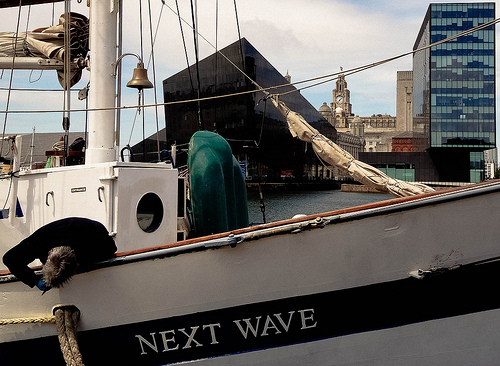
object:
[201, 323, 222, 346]
writing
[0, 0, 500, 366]
boat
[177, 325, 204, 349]
word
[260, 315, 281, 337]
word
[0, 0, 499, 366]
part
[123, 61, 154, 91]
bell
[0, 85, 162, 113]
clouds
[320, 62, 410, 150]
land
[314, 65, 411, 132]
building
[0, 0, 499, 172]
background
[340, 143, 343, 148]
windows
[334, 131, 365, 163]
building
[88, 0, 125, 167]
pole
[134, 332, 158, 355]
letters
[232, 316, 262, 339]
lettering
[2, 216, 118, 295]
man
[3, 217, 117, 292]
black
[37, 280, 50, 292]
glove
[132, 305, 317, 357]
next wave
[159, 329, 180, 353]
letters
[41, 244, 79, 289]
hair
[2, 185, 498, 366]
side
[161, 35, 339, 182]
building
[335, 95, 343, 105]
clock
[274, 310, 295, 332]
letter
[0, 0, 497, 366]
picture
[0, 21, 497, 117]
rope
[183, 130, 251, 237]
seat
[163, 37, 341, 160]
glass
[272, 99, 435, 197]
mast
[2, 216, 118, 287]
jacket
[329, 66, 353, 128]
clock tower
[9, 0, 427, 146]
sky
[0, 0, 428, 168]
harbor